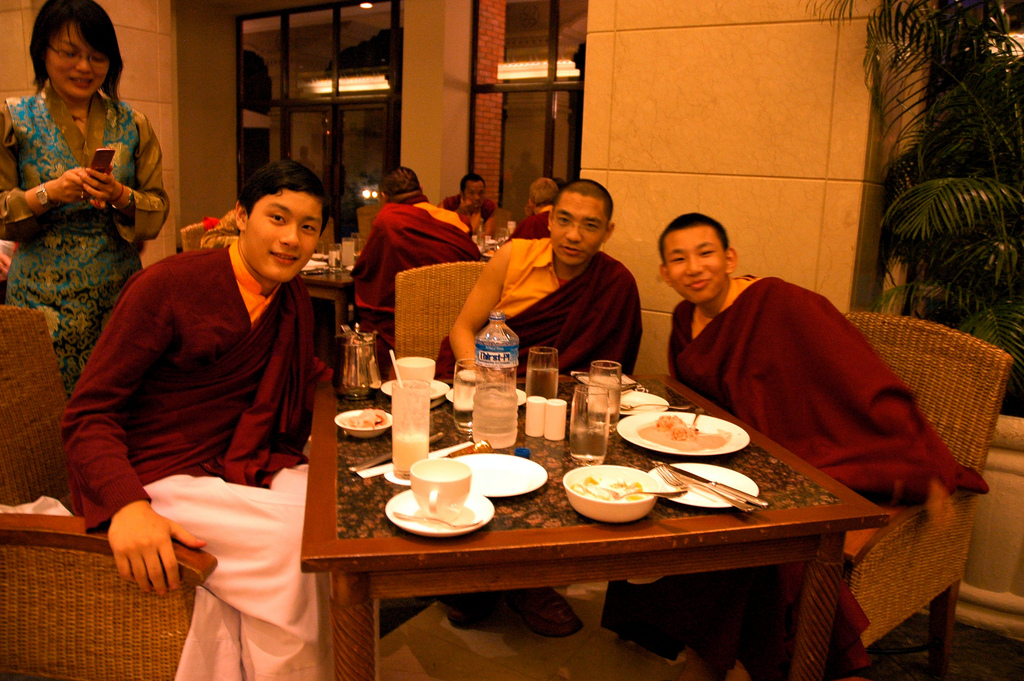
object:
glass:
[288, 13, 335, 99]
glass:
[239, 17, 278, 101]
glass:
[287, 112, 326, 196]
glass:
[339, 102, 394, 238]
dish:
[383, 487, 496, 537]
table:
[298, 370, 901, 680]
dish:
[451, 453, 549, 498]